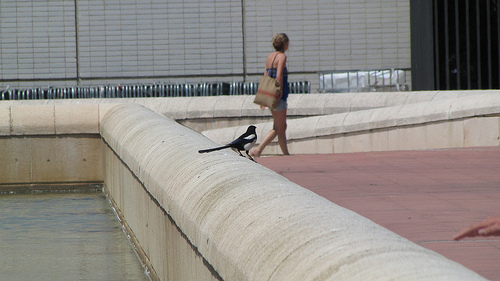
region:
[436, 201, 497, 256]
disembodied human hand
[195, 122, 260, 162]
black and white bird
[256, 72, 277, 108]
large tan canvas handbag with red stripe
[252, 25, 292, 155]
woman in shorts and halter top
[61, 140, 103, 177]
water outlet set in cement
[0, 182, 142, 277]
still dirty water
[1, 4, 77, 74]
grey bricks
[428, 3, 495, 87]
dark black windows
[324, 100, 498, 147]
cement railing sloped upwards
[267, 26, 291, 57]
head of a person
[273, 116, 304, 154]
leg of a person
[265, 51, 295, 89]
arm of a person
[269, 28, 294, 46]
hair of a person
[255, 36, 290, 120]
bag of a person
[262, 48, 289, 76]
back of a person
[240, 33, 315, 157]
person wearing tank top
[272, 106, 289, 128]
thigh of a person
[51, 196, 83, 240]
Part of the water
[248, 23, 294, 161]
A person walking on the ground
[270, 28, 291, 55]
The head of the person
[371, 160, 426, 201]
Part of the ground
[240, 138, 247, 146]
Part of the bird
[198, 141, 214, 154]
Part of the bird's tail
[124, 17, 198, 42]
Part of the building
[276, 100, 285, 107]
Part of the blue shorts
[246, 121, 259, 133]
The head of the bird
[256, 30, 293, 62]
the head of a woman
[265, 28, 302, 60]
the hair of a woman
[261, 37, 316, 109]
the arm of a woman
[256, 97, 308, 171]
the legs of a woman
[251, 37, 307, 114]
thw back of a woman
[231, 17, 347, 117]
a woman holding a purse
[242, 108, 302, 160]
the knees of a woman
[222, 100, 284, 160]
a little black bird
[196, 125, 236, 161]
the tail feather on a bird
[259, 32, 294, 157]
a person walking on a sidewalk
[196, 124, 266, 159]
a a brick in a building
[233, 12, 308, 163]
a woman is walking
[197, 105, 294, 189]
bird on a ledge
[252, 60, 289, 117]
woman carrying a bag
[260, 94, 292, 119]
woman is wearing shorts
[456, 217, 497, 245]
fingers on a hand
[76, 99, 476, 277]
the ledge is tan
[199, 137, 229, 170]
tail feather of birt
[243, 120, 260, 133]
black head of bird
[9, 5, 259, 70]
a tan brick wall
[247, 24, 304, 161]
a woman with a bag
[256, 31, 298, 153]
a woman carrying a bag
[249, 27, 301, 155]
a woman carrying a large bag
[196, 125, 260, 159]
a small black bird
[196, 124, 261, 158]
a black bird on a ledge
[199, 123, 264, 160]
a bird on a concrete wall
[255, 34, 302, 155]
a woman with brown hair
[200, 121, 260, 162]
a small black and white bird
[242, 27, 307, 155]
a woman in a skirt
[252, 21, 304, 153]
a woman walking in public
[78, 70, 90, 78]
white brick on wall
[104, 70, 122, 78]
white brick on wall